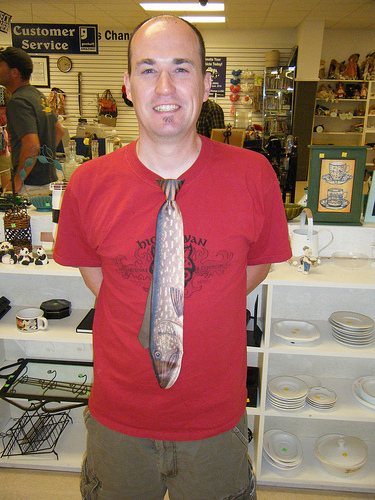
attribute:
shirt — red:
[90, 117, 299, 462]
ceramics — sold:
[284, 313, 372, 483]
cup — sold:
[15, 302, 55, 334]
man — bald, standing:
[67, 36, 321, 499]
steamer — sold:
[2, 409, 77, 471]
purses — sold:
[23, 70, 128, 147]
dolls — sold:
[298, 48, 374, 146]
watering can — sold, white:
[284, 207, 329, 262]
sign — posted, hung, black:
[6, 16, 112, 68]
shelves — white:
[253, 246, 375, 499]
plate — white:
[279, 298, 313, 352]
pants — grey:
[78, 397, 264, 500]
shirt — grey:
[6, 81, 53, 201]